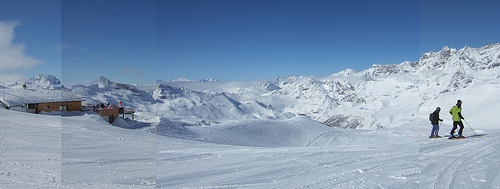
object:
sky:
[0, 0, 500, 84]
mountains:
[438, 69, 478, 95]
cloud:
[0, 19, 48, 83]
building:
[0, 85, 137, 123]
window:
[59, 105, 68, 111]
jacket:
[449, 104, 465, 122]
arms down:
[430, 111, 443, 125]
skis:
[447, 136, 457, 140]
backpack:
[428, 111, 437, 121]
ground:
[0, 109, 500, 189]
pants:
[430, 124, 440, 137]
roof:
[4, 89, 88, 104]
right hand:
[440, 119, 444, 122]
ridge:
[0, 43, 500, 87]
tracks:
[359, 158, 403, 172]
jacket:
[428, 109, 441, 125]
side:
[35, 101, 83, 114]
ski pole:
[462, 118, 480, 138]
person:
[428, 106, 444, 138]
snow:
[1, 45, 500, 187]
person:
[448, 99, 466, 140]